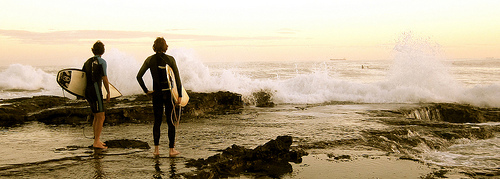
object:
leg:
[84, 91, 105, 142]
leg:
[152, 104, 164, 151]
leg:
[164, 101, 175, 150]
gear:
[82, 56, 108, 114]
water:
[0, 63, 500, 149]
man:
[83, 40, 112, 148]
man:
[137, 36, 183, 155]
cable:
[168, 66, 180, 127]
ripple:
[206, 113, 318, 128]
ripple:
[114, 165, 179, 172]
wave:
[0, 30, 500, 106]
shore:
[0, 91, 500, 179]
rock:
[184, 135, 308, 173]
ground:
[370, 97, 497, 175]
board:
[165, 64, 190, 107]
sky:
[4, 2, 497, 62]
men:
[81, 36, 185, 155]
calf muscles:
[153, 126, 161, 143]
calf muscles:
[168, 125, 175, 144]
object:
[0, 31, 500, 108]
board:
[55, 68, 122, 100]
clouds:
[1, 29, 301, 47]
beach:
[0, 91, 500, 179]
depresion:
[371, 99, 500, 128]